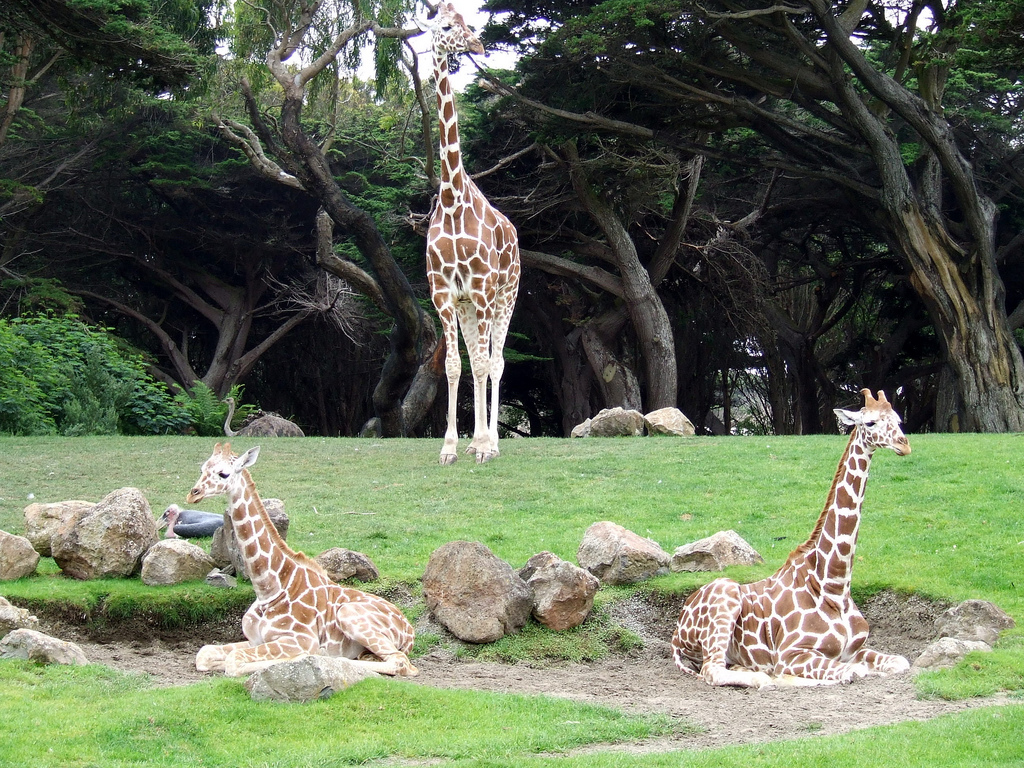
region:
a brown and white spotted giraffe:
[182, 430, 418, 684]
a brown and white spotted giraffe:
[662, 366, 918, 690]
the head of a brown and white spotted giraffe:
[181, 445, 258, 502]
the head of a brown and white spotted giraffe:
[412, 3, 490, 60]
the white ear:
[235, 446, 262, 469]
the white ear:
[409, 9, 432, 29]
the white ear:
[827, 404, 859, 425]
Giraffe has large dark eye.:
[435, 15, 458, 35]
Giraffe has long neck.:
[420, 56, 477, 218]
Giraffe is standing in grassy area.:
[424, 37, 542, 489]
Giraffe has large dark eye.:
[856, 414, 882, 441]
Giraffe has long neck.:
[803, 432, 870, 573]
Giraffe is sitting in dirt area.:
[666, 563, 892, 710]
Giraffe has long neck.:
[223, 456, 303, 584]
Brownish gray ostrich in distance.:
[215, 389, 298, 440]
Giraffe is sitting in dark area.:
[151, 455, 455, 715]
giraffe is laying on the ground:
[177, 443, 422, 674]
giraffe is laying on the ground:
[666, 378, 919, 682]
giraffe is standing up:
[393, 5, 542, 464]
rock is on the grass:
[517, 547, 595, 636]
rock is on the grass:
[574, 512, 677, 576]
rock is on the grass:
[672, 520, 752, 572]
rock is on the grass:
[580, 396, 645, 444]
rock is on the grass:
[641, 400, 698, 439]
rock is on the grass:
[138, 535, 218, 593]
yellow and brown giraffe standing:
[405, 2, 535, 471]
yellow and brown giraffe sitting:
[661, 377, 922, 706]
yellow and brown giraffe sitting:
[162, 423, 434, 700]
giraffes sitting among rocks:
[2, 382, 1021, 699]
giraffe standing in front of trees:
[1, 0, 1022, 466]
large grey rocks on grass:
[0, 388, 769, 673]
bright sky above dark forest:
[0, 3, 1022, 441]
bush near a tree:
[0, 0, 352, 443]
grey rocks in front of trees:
[538, 0, 717, 447]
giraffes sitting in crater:
[0, 377, 1022, 766]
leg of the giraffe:
[873, 655, 911, 668]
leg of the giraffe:
[181, 645, 249, 671]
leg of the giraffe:
[476, 433, 493, 466]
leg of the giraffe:
[485, 402, 511, 448]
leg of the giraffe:
[471, 372, 504, 417]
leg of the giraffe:
[285, 633, 347, 653]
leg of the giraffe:
[209, 654, 238, 665]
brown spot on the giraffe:
[835, 460, 856, 496]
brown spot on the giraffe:
[450, 201, 479, 236]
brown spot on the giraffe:
[434, 178, 455, 204]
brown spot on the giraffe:
[453, 226, 474, 261]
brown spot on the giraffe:
[428, 227, 455, 273]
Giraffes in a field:
[163, 9, 903, 709]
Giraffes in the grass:
[138, 7, 939, 703]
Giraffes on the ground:
[142, 408, 945, 694]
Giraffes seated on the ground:
[152, 430, 883, 713]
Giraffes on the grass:
[168, 436, 952, 670]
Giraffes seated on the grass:
[170, 385, 918, 698]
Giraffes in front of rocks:
[155, 380, 925, 701]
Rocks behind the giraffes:
[22, 496, 947, 668]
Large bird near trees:
[212, 380, 317, 437]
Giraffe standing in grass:
[407, 15, 575, 464]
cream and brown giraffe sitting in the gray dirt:
[187, 438, 419, 682]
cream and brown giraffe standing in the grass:
[416, 3, 527, 469]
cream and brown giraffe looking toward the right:
[410, 2, 522, 471]